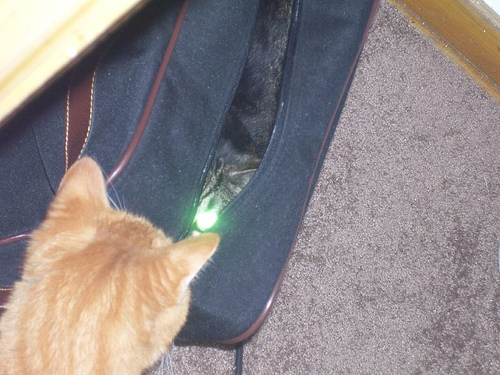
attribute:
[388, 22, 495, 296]
floor — carpeted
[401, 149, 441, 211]
carpet — brown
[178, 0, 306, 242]
zipper — open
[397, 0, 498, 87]
wall — wooden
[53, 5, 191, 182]
lining — purple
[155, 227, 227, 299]
ear — right ear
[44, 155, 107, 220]
ear — orange, white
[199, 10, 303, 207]
cat — black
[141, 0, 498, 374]
carpet — brown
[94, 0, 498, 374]
floor — carpeted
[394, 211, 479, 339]
rug — gray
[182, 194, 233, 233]
light — green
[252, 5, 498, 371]
carpet — brown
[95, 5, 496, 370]
carpet — gray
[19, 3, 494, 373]
carpet — blue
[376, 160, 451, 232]
floor — carpeted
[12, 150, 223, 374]
head — small, brown, white, orange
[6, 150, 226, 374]
cat — orange, rust colored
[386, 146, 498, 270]
patch — small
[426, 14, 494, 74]
baseboard — brown, wood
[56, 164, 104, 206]
ear — left ear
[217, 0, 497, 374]
carpet — brown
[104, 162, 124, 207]
whiskers — white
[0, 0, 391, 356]
back back — brown, blue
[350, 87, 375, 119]
brown patch — small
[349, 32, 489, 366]
carpet — brown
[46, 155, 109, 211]
ear — right ear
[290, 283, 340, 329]
patch — small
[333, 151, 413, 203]
patch — small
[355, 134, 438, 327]
carpet — brown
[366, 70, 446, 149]
patch — small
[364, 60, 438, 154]
patch — small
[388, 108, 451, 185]
patch — small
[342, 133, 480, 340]
carpet — brown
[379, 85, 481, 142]
patch — small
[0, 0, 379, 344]
bag — blue, brown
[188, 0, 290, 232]
cat — black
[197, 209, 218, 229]
eye — reflecting light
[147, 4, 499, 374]
floor — carpeted